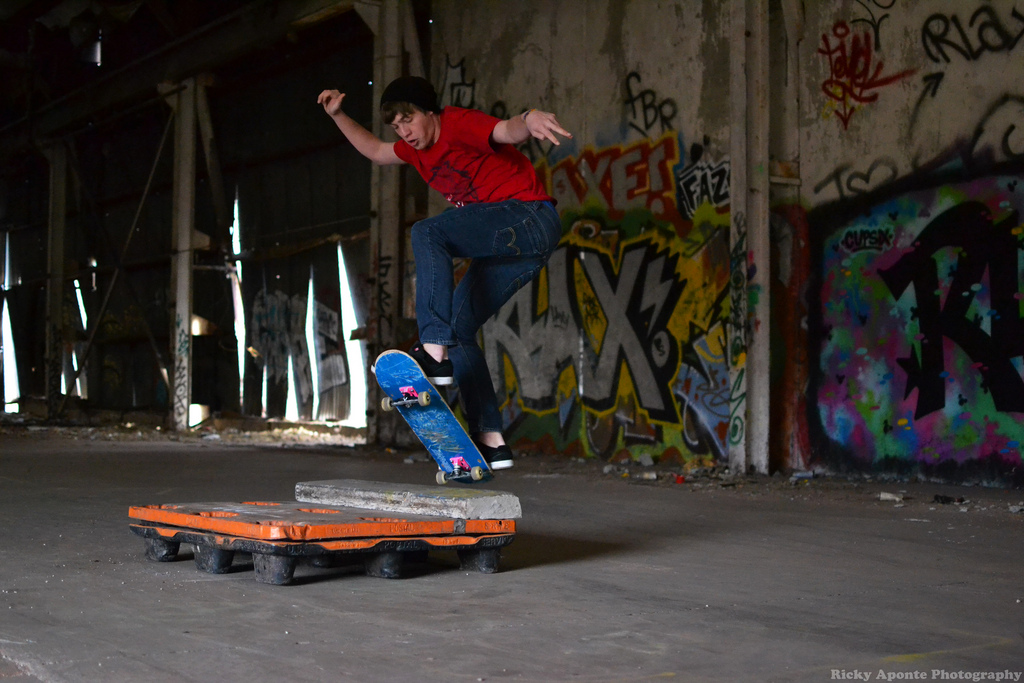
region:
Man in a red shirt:
[310, 76, 573, 470]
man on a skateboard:
[316, 66, 572, 493]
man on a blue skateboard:
[309, 54, 573, 488]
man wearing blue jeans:
[313, 72, 579, 466]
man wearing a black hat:
[319, 75, 579, 475]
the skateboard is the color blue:
[370, 348, 497, 494]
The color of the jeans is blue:
[408, 196, 563, 434]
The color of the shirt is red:
[392, 113, 545, 206]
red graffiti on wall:
[814, 10, 919, 127]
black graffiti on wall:
[910, 10, 1021, 64]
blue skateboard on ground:
[363, 350, 507, 491]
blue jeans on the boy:
[413, 192, 566, 402]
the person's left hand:
[515, 98, 570, 156]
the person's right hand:
[314, 83, 363, 116]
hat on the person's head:
[366, 75, 447, 111]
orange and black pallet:
[129, 474, 532, 591]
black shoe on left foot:
[409, 350, 461, 386]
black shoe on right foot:
[477, 432, 520, 472]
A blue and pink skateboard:
[374, 353, 493, 484]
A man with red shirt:
[313, 81, 574, 467]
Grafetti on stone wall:
[779, 8, 1021, 483]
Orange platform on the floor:
[124, 467, 537, 588]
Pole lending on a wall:
[150, 84, 209, 436]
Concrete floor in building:
[0, 391, 307, 491]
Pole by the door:
[30, 88, 75, 430]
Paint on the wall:
[558, 88, 742, 480]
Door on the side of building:
[216, 29, 376, 431]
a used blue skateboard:
[362, 348, 499, 482]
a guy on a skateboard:
[313, 69, 582, 482]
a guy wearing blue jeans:
[319, 73, 572, 466]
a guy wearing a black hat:
[313, 70, 577, 478]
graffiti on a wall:
[556, 148, 1022, 484]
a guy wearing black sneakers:
[319, 70, 582, 475]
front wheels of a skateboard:
[376, 382, 438, 415]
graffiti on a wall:
[863, 190, 1016, 424]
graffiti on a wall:
[788, 188, 913, 354]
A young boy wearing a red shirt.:
[395, 97, 536, 206]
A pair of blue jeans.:
[386, 202, 561, 450]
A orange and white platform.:
[78, 459, 531, 593]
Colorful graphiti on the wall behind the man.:
[575, 139, 760, 473]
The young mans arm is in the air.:
[483, 98, 576, 152]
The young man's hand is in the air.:
[310, 82, 358, 136]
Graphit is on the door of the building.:
[236, 281, 353, 403]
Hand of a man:
[522, 104, 576, 158]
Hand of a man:
[315, 83, 351, 119]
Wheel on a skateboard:
[375, 388, 398, 417]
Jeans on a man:
[411, 196, 574, 441]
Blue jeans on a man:
[407, 202, 575, 441]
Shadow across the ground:
[527, 500, 651, 590]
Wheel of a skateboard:
[413, 388, 436, 411]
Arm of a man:
[344, 119, 402, 177]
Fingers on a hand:
[546, 121, 576, 157]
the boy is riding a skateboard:
[301, 66, 590, 478]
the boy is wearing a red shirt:
[315, 62, 576, 208]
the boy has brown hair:
[370, 73, 443, 156]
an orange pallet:
[132, 493, 513, 560]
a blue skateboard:
[372, 348, 486, 481]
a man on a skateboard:
[326, 76, 560, 484]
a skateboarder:
[332, 86, 561, 482]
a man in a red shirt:
[329, 92, 542, 394]